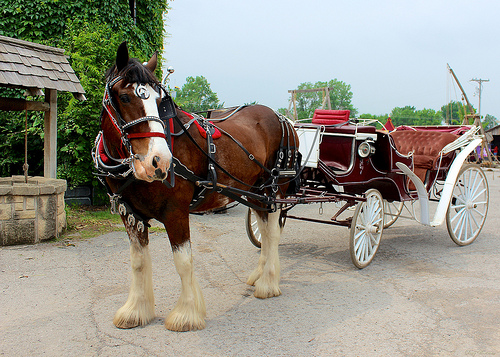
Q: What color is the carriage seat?
A: Maroon.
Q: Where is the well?
A: Beside the horse.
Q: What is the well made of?
A: Brick and wood.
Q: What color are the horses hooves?
A: White.